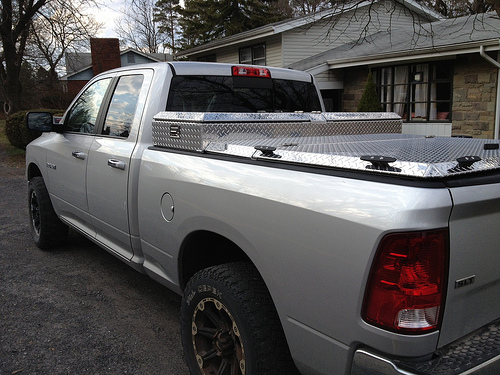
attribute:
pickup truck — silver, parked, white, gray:
[25, 62, 497, 373]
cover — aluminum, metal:
[209, 140, 498, 178]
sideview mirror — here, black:
[25, 113, 54, 132]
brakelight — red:
[360, 230, 448, 333]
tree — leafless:
[3, 0, 48, 120]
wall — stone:
[340, 55, 500, 136]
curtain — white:
[377, 68, 438, 119]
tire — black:
[178, 259, 292, 374]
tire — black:
[28, 178, 69, 249]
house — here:
[175, 2, 499, 138]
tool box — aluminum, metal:
[151, 110, 401, 150]